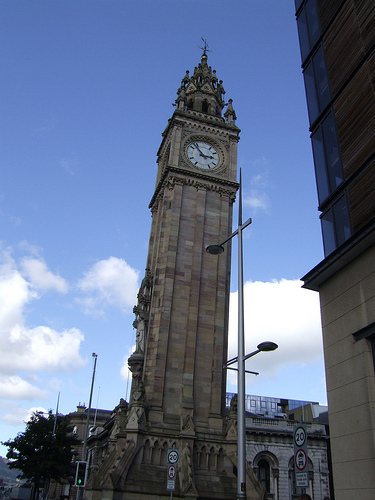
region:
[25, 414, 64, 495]
A tree next to the building.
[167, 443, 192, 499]
A sign in front of the tower.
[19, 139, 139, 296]
The sky is clear and blue.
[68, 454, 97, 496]
The traffic signal light is green.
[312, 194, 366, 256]
The building has a window.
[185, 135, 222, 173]
clock is white and black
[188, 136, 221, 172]
time is 3:53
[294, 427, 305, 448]
sign has green and white area with a 20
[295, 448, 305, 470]
sign has a bus symbol on it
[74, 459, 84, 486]
stop light is green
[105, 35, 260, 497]
clock tower is tall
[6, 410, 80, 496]
tree is dark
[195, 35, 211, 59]
weather vane on top of the clock tower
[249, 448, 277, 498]
arched doorways on building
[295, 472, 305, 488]
black writing on sign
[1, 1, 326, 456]
clouds in blue sky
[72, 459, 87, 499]
glowing green traffic light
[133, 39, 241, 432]
tower with white clock face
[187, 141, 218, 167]
two hands of clock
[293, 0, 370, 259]
windows on corner of building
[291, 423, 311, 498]
signs on top of pole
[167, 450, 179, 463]
number in white circle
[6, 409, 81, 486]
green leaves on tree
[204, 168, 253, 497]
light on metal pole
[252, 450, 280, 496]
arched doorway of building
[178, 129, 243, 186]
an outside clock on a building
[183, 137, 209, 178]
a large clock on a budiling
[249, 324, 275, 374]
a light on a pole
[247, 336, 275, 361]
a light on a metal pole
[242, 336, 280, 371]
a pole with a light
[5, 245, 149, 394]
a skyw ith clouds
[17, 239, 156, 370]
a sky with white clouds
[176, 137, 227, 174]
Clock face on a tower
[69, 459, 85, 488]
Traffic light with green signal lit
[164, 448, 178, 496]
A sign on a pole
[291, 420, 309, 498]
A sign on a pole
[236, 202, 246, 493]
A tall metal pole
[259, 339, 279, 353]
Domed street light on a pole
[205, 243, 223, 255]
Domed street light on a pole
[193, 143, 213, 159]
Black hands on a clock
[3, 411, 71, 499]
Tree growing near a building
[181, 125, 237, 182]
A clock on the tower.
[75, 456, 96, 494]
The traffic light is green.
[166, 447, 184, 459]
A sign with number 20 in the circle.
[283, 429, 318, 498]
Three signs on the pole.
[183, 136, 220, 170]
A round clock on the tower.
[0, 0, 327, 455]
A blue sky with white clouds.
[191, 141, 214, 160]
Black hands on a clock.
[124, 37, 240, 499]
A large leaning clock tower.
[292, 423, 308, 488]
Largest rectangle sign with a 20 on the top in a circle.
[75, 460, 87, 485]
Black traffic light with green lit up.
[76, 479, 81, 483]
A green round light.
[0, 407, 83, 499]
A green leafy tree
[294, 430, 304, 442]
Largest number 20 on a sign.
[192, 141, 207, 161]
Big black hand of a clock.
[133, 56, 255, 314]
A very tall clock tower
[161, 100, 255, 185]
A clock on a tower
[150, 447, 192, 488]
These limits on the street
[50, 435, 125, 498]
A stop light that shows a green light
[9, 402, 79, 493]
A tall green tree next to the clock tower